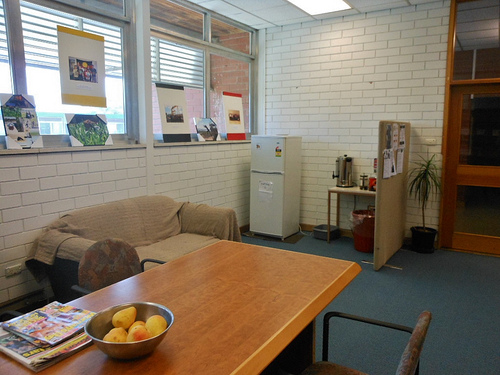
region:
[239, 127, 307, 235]
a refrigerator in a brake room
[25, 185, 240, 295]
a brown sofa on the wall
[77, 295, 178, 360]
pears in a stainless steel bowl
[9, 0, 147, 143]
a window in a room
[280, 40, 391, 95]
the bricks on of wall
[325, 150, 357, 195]
a coffee pot on a table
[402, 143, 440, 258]
a house plant in a corner of a room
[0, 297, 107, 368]
a stack of papers and magazines on a table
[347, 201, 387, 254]
a trash can under a table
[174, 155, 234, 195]
the bricks of a wall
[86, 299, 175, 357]
Silver bowl on table.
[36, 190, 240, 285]
Love seat against wall.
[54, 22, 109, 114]
Picture on white and yellow canvas.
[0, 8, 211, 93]
Blinds on windows.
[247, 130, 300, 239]
Small white refrigerator in corner.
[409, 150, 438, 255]
Green plant in black pot.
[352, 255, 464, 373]
Blue carpet on floor.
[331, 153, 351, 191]
Black and silver container.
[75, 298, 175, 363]
Pears in silver bowl.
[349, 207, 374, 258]
Clear trash bag in maroon trash can.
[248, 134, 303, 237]
a small white refrigerator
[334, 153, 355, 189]
a coffee urn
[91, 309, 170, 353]
fruit in a metal bowl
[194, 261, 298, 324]
a wooden table top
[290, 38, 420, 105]
a white brick wall in a building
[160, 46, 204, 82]
blinds on the window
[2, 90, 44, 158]
artwork on a windowsill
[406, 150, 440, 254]
a plant in a black pot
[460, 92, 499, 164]
glass pane in a door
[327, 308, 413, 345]
the metal armrest of a chair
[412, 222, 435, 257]
the pot is black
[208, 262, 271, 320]
the table is brown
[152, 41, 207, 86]
the blinds are open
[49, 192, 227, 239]
the couch is covered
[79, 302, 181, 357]
the fruit is in the bowl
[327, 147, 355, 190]
the coffee urn is on the table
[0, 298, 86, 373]
the magazines are on the table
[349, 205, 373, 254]
the garbage pail is red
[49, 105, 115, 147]
the picture is on the window seal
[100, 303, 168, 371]
yellow fruit in a metal bowl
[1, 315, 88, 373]
magazines on wooden table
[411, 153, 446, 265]
thin plant in pot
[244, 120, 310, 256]
tiny white refrigerator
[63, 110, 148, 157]
photo sitting on window ledge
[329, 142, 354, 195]
silver coffee pot on table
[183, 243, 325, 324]
long wooden table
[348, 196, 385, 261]
red trash container with bag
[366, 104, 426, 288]
light brown partition against wall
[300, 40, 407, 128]
white brick wall in distance